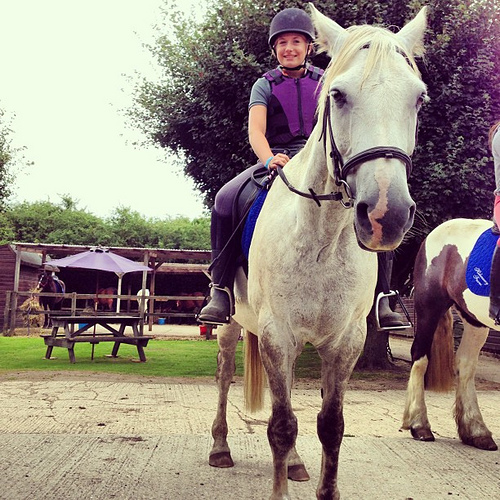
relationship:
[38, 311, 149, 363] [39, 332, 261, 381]
bench on grass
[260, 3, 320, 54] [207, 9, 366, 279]
helmet on woman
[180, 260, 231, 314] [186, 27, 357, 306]
boots on woman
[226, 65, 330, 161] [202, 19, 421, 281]
tshirt on woman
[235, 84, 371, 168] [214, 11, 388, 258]
vest on woman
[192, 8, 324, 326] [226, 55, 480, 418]
lady on horse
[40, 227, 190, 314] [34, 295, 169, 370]
umbrella on table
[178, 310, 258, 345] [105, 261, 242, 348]
bucket by fence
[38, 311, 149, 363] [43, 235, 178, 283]
bench by umbrella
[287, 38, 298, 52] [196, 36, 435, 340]
nose of woman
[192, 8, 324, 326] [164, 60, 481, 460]
lady riding horse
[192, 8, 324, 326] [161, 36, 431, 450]
lady riding horse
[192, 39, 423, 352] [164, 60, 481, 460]
lady riding horse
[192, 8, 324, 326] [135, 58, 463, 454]
lady riding horse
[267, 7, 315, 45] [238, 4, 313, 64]
helmet on head